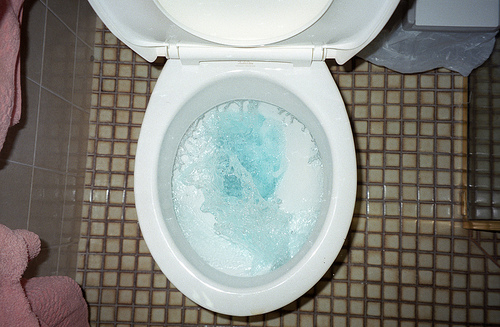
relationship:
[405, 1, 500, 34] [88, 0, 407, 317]
bin beside toilet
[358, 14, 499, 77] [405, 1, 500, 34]
bag in bin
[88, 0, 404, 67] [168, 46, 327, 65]
seat has hinge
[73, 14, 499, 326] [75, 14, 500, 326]
floor has tiles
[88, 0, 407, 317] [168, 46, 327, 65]
toilet has hinge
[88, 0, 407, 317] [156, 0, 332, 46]
toilet has lid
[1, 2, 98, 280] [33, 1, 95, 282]
wall has reflection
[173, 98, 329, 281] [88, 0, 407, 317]
water in toilet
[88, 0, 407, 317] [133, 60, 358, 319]
toilet has bowl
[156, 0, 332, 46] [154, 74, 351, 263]
lid visible through seat